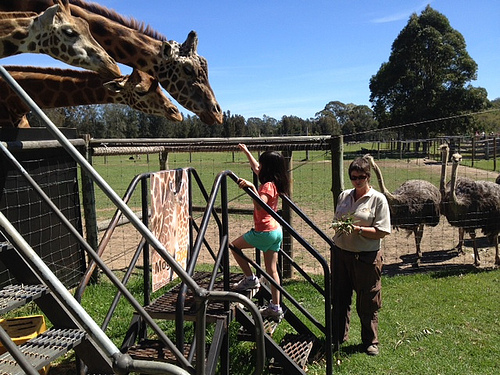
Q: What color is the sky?
A: Blue.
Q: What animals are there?
A: Giraffes.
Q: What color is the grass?
A: Green.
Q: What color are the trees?
A: Dark Green.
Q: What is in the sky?
A: Clouds.